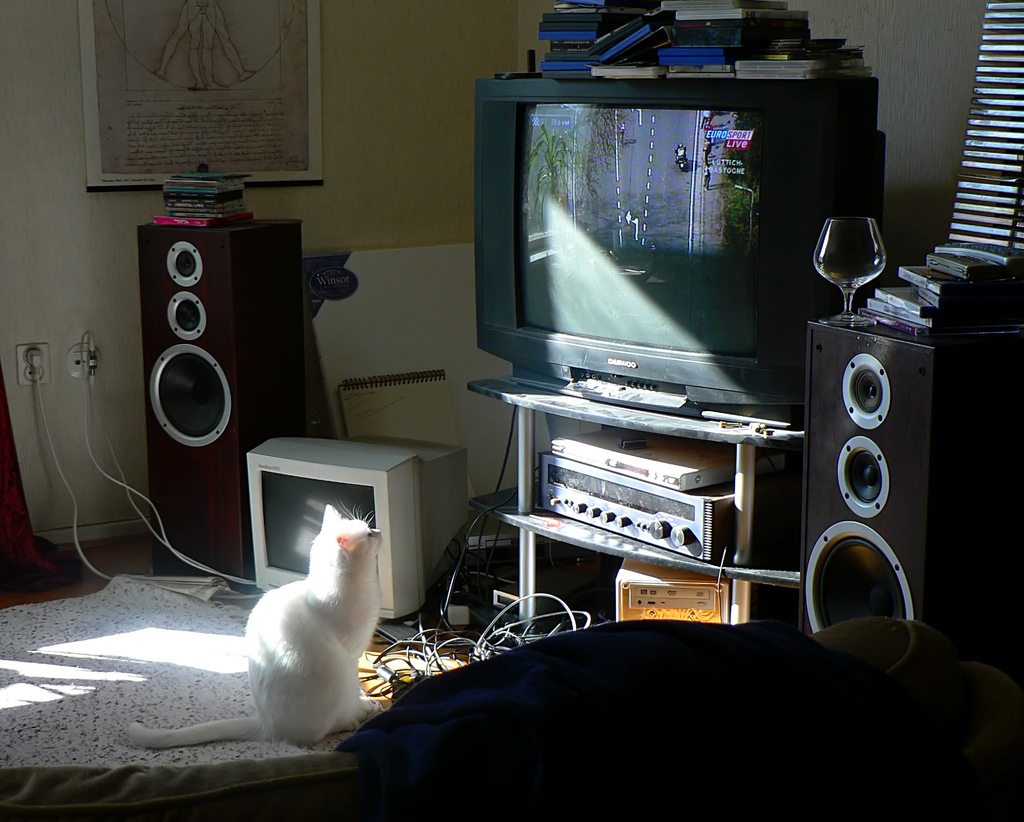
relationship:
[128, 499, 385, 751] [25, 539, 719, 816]
cat sitting on floor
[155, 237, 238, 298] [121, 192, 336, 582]
part of speaker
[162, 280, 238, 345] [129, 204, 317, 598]
part of speaker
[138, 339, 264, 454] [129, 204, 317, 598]
part of speaker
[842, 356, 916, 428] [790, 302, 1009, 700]
part of speaker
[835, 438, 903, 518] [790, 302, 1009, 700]
part of speaker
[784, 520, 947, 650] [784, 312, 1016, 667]
part of speaker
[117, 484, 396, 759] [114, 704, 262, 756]
cat has tail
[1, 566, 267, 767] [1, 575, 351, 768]
spots on rug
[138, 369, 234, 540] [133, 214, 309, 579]
large brown rectangular stereo speaker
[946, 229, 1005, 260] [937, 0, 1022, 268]
cd on rack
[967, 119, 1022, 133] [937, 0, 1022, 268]
cd on rack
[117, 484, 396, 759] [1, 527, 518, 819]
cat on floor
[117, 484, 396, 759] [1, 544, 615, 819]
cat on floor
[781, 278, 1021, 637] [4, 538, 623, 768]
speaker on floor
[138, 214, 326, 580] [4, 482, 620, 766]
speaker on floor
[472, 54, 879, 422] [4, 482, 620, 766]
tv on floor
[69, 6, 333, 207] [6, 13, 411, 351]
painting on wall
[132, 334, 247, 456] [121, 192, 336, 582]
circle on speaker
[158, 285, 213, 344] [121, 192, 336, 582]
circle on speaker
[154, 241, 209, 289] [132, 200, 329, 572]
circle on speaker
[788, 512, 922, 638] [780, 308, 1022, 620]
circle on speaker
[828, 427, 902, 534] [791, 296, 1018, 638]
circle on speaker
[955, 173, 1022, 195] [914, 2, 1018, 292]
cd on rack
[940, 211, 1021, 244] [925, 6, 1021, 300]
cd on rack